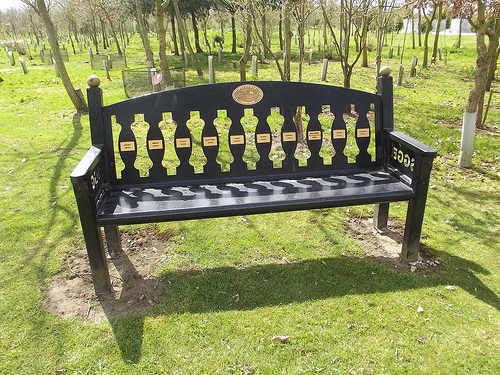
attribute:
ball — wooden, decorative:
[86, 72, 101, 87]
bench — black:
[68, 68, 440, 291]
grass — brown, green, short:
[1, 29, 499, 275]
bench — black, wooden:
[93, 83, 391, 237]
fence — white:
[397, 17, 475, 37]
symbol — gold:
[220, 79, 262, 114]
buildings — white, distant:
[386, 11, 471, 39]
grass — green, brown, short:
[5, 34, 497, 374]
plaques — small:
[354, 104, 371, 164]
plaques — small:
[329, 107, 350, 167]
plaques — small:
[303, 105, 324, 167]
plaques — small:
[278, 104, 296, 166]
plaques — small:
[247, 107, 274, 169]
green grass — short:
[0, 30, 499, 373]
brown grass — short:
[1, 40, 498, 372]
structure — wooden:
[390, 15, 475, 32]